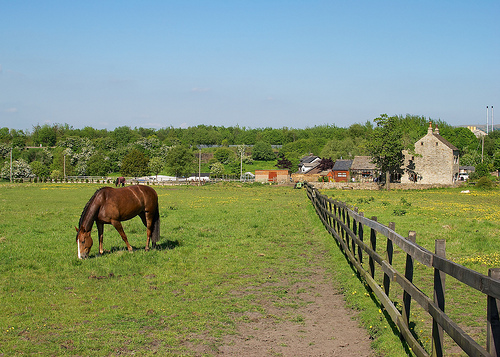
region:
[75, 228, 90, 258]
The head of a horse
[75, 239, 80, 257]
A white stripe on the head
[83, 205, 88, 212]
The mane on the neck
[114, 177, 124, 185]
A horse browsing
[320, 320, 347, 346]
A bare patch of the grass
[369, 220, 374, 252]
A wooden fence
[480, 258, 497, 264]
Yellow flowers in the grass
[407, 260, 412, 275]
Shadow on the wood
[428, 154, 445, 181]
Sun reflecting on a building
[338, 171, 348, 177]
White windows on a building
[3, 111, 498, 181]
hillside filled with shrubbery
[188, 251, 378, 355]
dirt patch in pasture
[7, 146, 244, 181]
line of four utility poles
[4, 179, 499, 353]
pasture land divided by fence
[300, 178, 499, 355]
post and board fencing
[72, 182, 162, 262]
brown and white horse grazing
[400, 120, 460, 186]
stucco building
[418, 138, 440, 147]
two tiny windows in stucco building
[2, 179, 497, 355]
fields strewn with yellow wildflowers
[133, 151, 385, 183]
row of farm buildings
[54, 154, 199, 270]
Horse on the ground.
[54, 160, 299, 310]
Horse on the grass.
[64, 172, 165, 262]
Brown horse on the grass.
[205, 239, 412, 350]
Dirt on the grass.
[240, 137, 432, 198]
Buildings in the background.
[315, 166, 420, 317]
Fence on the grass.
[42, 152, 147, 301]
Horse with a white nose.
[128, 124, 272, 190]
Trees in the background.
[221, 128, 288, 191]
Power lines in the background.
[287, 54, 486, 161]
Blue sky above the trees.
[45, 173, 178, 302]
brown horse eating grass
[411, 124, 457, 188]
white barn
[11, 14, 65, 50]
white clouds in blue sky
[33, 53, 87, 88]
white clouds in blue sky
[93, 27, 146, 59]
white clouds in blue sky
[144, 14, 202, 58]
white clouds in blue sky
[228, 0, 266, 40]
white clouds in blue sky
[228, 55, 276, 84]
white clouds in blue sky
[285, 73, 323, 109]
white clouds in blue sky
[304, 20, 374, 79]
white clouds in blue sky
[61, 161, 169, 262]
brown and white horse in a grass field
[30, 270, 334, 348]
grass and dirt field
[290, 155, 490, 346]
wooden fence in a field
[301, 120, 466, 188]
houses in a field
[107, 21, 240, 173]
clear blue sky behind green trees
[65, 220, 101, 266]
white stripe on a brown horse's nose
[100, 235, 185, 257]
shadow of a horse in a field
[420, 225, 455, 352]
wooden fence post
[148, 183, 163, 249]
tail of a brown horse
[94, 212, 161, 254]
legs of a brown horse